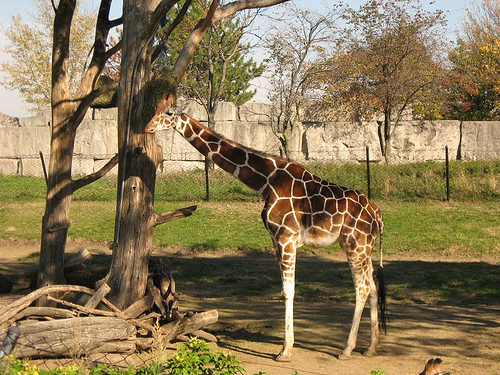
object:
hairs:
[374, 266, 387, 335]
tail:
[375, 233, 391, 337]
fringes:
[376, 265, 390, 337]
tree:
[288, 0, 464, 167]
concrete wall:
[0, 95, 500, 177]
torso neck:
[172, 109, 387, 362]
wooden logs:
[9, 277, 187, 364]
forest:
[0, 0, 498, 172]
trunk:
[30, 12, 92, 322]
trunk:
[102, 2, 160, 300]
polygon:
[266, 167, 294, 200]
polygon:
[289, 178, 306, 197]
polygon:
[267, 197, 293, 226]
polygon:
[285, 161, 306, 181]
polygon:
[289, 195, 312, 213]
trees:
[420, 0, 499, 121]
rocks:
[457, 116, 500, 162]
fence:
[4, 143, 496, 203]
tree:
[140, 0, 270, 205]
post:
[442, 145, 451, 201]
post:
[364, 145, 373, 200]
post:
[201, 155, 213, 202]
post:
[37, 150, 47, 182]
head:
[142, 87, 188, 135]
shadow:
[407, 256, 500, 367]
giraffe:
[144, 90, 388, 362]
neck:
[179, 118, 264, 190]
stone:
[374, 119, 463, 163]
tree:
[71, 0, 286, 328]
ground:
[2, 169, 495, 372]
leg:
[274, 242, 296, 348]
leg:
[348, 241, 381, 347]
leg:
[341, 242, 373, 353]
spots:
[363, 203, 379, 221]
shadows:
[0, 249, 286, 347]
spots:
[344, 226, 372, 248]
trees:
[38, 0, 193, 320]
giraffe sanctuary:
[1, 94, 498, 373]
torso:
[261, 154, 381, 257]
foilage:
[309, 3, 441, 128]